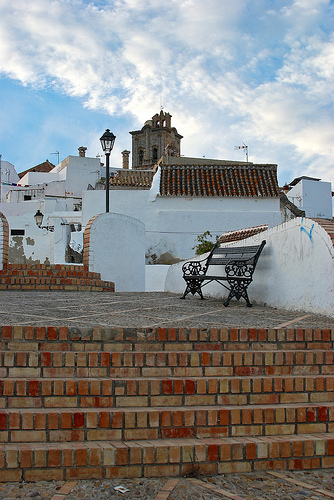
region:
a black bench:
[179, 235, 275, 303]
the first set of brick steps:
[5, 315, 330, 448]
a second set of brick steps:
[6, 253, 117, 289]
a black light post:
[95, 120, 130, 218]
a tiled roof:
[153, 158, 290, 196]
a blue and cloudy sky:
[14, 7, 326, 107]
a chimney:
[74, 143, 90, 165]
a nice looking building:
[127, 105, 186, 168]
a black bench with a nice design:
[174, 229, 266, 307]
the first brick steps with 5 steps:
[5, 312, 329, 459]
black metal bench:
[176, 239, 269, 307]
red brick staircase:
[2, 254, 114, 296]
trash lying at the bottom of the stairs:
[109, 481, 133, 495]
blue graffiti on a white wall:
[296, 214, 317, 249]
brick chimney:
[120, 148, 131, 171]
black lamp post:
[97, 125, 118, 215]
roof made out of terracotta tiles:
[159, 161, 282, 200]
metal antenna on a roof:
[47, 148, 63, 162]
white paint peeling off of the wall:
[5, 233, 53, 264]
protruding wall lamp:
[33, 207, 57, 234]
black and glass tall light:
[99, 126, 113, 212]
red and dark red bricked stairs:
[0, 323, 329, 472]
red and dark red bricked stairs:
[1, 261, 112, 290]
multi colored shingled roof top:
[158, 165, 277, 198]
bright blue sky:
[2, 2, 333, 185]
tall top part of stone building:
[128, 102, 179, 167]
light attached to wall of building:
[33, 209, 52, 230]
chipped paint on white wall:
[8, 235, 48, 262]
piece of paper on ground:
[114, 485, 128, 492]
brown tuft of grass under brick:
[183, 454, 214, 475]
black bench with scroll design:
[183, 236, 282, 304]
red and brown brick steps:
[6, 319, 319, 484]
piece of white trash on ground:
[111, 480, 132, 495]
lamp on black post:
[93, 129, 122, 215]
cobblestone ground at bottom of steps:
[13, 473, 329, 497]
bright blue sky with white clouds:
[0, 11, 323, 151]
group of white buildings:
[17, 162, 307, 269]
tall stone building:
[124, 105, 182, 163]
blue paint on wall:
[292, 217, 326, 247]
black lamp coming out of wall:
[32, 207, 58, 233]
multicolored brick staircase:
[8, 325, 148, 478]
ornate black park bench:
[180, 237, 265, 306]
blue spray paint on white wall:
[295, 213, 324, 242]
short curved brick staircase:
[2, 253, 120, 296]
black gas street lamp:
[98, 124, 118, 212]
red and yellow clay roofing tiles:
[156, 161, 285, 202]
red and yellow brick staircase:
[69, 321, 316, 478]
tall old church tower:
[129, 108, 180, 171]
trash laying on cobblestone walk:
[111, 480, 134, 498]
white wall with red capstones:
[80, 210, 150, 290]